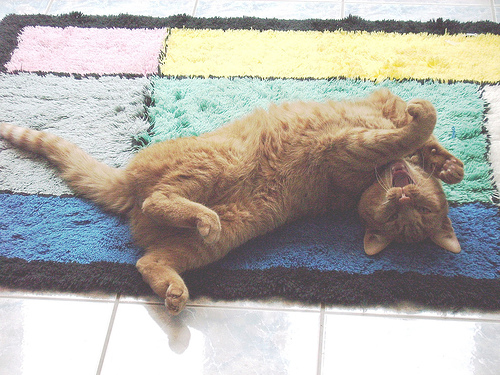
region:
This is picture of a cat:
[61, 89, 496, 266]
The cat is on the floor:
[107, 91, 304, 271]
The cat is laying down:
[140, 154, 247, 277]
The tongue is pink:
[339, 138, 424, 247]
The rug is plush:
[197, 87, 235, 123]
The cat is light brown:
[158, 161, 281, 247]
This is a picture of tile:
[244, 332, 287, 371]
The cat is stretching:
[200, 137, 312, 224]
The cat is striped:
[223, 135, 381, 202]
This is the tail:
[10, 103, 130, 238]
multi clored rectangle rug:
[1, 17, 496, 309]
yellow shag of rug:
[160, 29, 496, 76]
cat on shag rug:
[2, 89, 470, 314]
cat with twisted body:
[0, 90, 465, 320]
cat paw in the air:
[357, 97, 464, 253]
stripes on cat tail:
[1, 123, 130, 209]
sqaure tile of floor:
[102, 301, 326, 373]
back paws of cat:
[136, 195, 222, 313]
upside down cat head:
[360, 159, 462, 256]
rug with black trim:
[0, 14, 497, 307]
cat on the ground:
[43, 68, 486, 293]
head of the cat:
[356, 156, 461, 250]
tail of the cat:
[3, 108, 138, 212]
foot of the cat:
[133, 258, 197, 323]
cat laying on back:
[48, 95, 477, 350]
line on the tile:
[276, 313, 363, 367]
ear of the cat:
[425, 219, 471, 265]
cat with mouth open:
[341, 150, 466, 275]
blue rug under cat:
[287, 219, 358, 261]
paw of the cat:
[423, 143, 472, 195]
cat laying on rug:
[2, 90, 465, 306]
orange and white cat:
[1, 89, 463, 307]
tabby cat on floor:
[0, 86, 462, 306]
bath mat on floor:
[2, 11, 498, 306]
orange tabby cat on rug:
[1, 93, 461, 308]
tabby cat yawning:
[1, 91, 464, 309]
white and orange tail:
[2, 121, 130, 216]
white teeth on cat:
[390, 164, 407, 171]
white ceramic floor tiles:
[1, 290, 498, 370]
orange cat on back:
[1, 90, 465, 307]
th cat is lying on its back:
[25, 82, 487, 293]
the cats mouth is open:
[384, 159, 421, 194]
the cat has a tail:
[9, 131, 104, 193]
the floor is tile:
[249, 316, 424, 354]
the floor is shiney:
[291, 316, 491, 373]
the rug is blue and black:
[20, 224, 85, 285]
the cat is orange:
[23, 89, 496, 314]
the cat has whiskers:
[417, 159, 435, 191]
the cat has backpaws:
[135, 180, 232, 317]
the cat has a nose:
[391, 192, 416, 206]